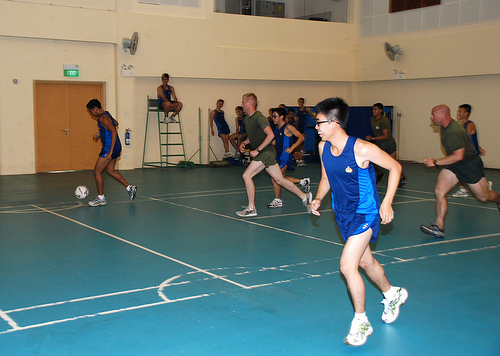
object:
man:
[307, 94, 411, 349]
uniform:
[320, 133, 382, 242]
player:
[85, 97, 139, 208]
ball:
[74, 184, 91, 200]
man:
[417, 102, 500, 240]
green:
[440, 119, 478, 166]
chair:
[139, 93, 190, 171]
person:
[208, 98, 241, 160]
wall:
[0, 0, 358, 174]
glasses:
[314, 118, 340, 127]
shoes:
[343, 315, 376, 348]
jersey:
[319, 135, 383, 216]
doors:
[33, 79, 71, 174]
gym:
[1, 0, 498, 354]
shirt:
[243, 110, 278, 157]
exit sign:
[62, 64, 80, 77]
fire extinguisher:
[124, 127, 131, 145]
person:
[156, 72, 183, 124]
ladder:
[154, 104, 189, 173]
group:
[85, 89, 500, 350]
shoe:
[419, 221, 446, 239]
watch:
[432, 157, 441, 170]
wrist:
[254, 146, 263, 154]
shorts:
[249, 146, 280, 169]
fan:
[121, 29, 140, 56]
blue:
[273, 121, 295, 171]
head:
[429, 103, 452, 127]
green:
[63, 69, 79, 78]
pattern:
[1, 179, 498, 338]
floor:
[0, 157, 500, 356]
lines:
[77, 223, 151, 253]